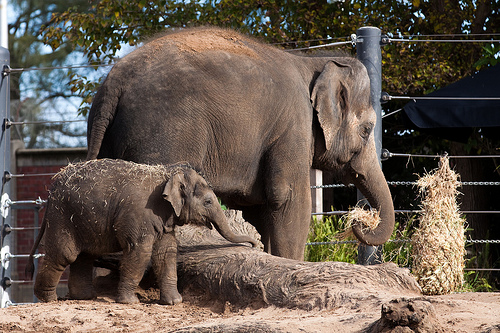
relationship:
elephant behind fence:
[88, 25, 396, 263] [2, 21, 499, 299]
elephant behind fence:
[25, 156, 263, 306] [2, 21, 499, 299]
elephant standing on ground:
[25, 156, 263, 306] [3, 286, 495, 331]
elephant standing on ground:
[88, 25, 396, 263] [3, 286, 495, 331]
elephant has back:
[25, 156, 263, 306] [53, 149, 140, 181]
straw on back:
[49, 158, 163, 190] [53, 149, 140, 181]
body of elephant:
[57, 146, 169, 260] [56, 162, 172, 237]